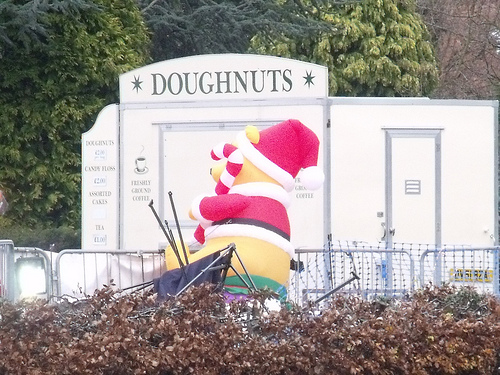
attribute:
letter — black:
[166, 71, 181, 94]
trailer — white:
[79, 52, 496, 294]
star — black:
[131, 75, 142, 90]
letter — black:
[248, 67, 270, 102]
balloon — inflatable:
[165, 118, 319, 313]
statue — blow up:
[150, 74, 326, 323]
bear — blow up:
[187, 124, 323, 298]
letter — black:
[213, 66, 235, 98]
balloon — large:
[126, 82, 365, 341]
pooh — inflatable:
[161, 116, 323, 310]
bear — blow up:
[163, 112, 322, 302]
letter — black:
[281, 67, 294, 92]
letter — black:
[234, 70, 249, 92]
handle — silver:
[388, 227, 393, 238]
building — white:
[319, 52, 499, 299]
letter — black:
[134, 54, 315, 109]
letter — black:
[264, 67, 281, 93]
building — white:
[75, 49, 484, 294]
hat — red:
[248, 130, 319, 178]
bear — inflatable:
[201, 128, 309, 283]